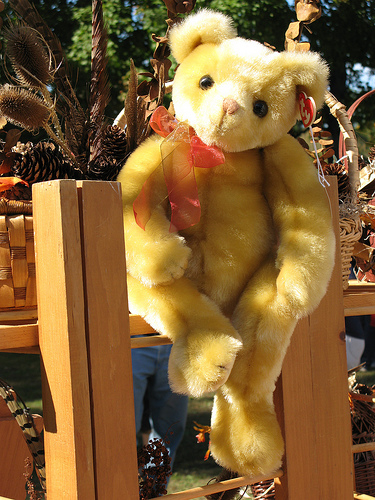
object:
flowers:
[0, 168, 28, 201]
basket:
[0, 198, 36, 324]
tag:
[296, 91, 319, 129]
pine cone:
[7, 139, 79, 181]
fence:
[0, 174, 373, 499]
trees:
[328, 3, 373, 93]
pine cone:
[87, 119, 130, 179]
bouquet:
[8, 3, 169, 171]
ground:
[183, 406, 209, 492]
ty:
[297, 90, 315, 128]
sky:
[351, 68, 367, 87]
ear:
[283, 44, 331, 121]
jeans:
[129, 346, 187, 493]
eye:
[196, 73, 219, 96]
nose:
[218, 92, 239, 119]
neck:
[170, 113, 290, 157]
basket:
[313, 88, 361, 293]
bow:
[131, 105, 227, 232]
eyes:
[250, 98, 268, 119]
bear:
[111, 10, 330, 479]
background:
[0, 3, 372, 219]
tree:
[106, 3, 148, 81]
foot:
[211, 402, 283, 483]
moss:
[336, 177, 359, 220]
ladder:
[30, 171, 139, 494]